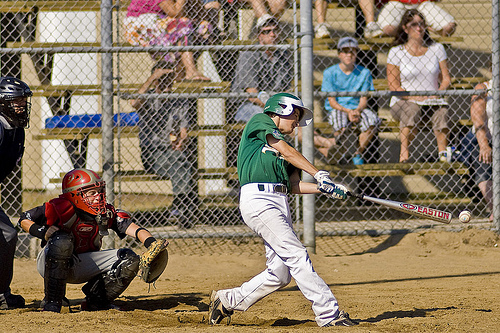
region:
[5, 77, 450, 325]
young boys playing baseball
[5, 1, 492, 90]
parents in background watching baseball game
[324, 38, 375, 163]
young boy in grey and blue outfit watching baseball game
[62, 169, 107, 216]
helmet of back catcher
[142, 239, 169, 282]
glove of backcatcher ready to catch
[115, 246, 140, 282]
knee pad of back catcher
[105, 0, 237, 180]
metal fence in background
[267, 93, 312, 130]
head of baseball player hitting ball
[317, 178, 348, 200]
hands of baseball player hitting ball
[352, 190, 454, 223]
swinging baseball bat in basseball players hands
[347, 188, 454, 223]
silver bat with a black grip and red writing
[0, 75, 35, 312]
referee dressed all in black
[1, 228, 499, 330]
brown dirt baseball field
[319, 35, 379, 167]
young male spectator wearing a blue shirt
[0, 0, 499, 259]
grey chain link fence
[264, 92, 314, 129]
green and white batter helmet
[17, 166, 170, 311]
player paying the catcher position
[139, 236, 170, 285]
leather catchers mitt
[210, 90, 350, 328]
player playing the batter position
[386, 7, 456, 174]
female spectator in a white shirt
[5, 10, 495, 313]
a baseball game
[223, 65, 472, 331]
A batter swinging a bat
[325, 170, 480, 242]
A baseball bat and ball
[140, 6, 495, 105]
Spectators at a baseball game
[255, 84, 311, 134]
A green helmet on a boy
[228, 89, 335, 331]
A baseball uniform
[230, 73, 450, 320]
A boy swining a baseball bat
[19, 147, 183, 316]
A catcher at a baseball game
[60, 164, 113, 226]
A catcher's mask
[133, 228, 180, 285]
A catcher's mitt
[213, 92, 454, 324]
a baseball player swinging a bat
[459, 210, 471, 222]
a white ball with red stitching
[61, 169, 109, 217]
a red catcher's mask with golden lines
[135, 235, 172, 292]
a torn leather catcher's mitt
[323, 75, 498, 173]
people sitting in the bleachers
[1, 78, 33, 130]
an umpire wearing a black mask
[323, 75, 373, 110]
a person wearing a blue T-shirt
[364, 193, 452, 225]
a silver baseball bat with a red logo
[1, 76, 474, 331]
men playing baseball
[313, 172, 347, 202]
a man wearing white gloves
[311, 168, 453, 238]
a metal baseball bat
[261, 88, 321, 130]
a baseball helmet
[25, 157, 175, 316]
a baseball catcher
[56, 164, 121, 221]
a baseball catcher's helmet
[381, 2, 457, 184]
a woman sitting down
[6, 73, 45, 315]
the umpire at a baseball game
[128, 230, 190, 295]
a baseball catcher's mitt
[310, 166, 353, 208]
baseball player's batting gloves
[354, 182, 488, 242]
a baseball being hit by a bat